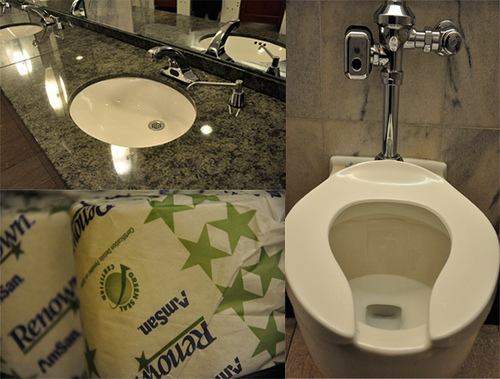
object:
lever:
[436, 20, 462, 60]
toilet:
[286, 1, 498, 377]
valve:
[333, 3, 466, 168]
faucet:
[143, 43, 200, 91]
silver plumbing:
[346, 0, 463, 162]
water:
[367, 300, 403, 330]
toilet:
[277, 131, 499, 376]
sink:
[1, 0, 58, 42]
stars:
[140, 187, 281, 358]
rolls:
[0, 195, 285, 372]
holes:
[243, 35, 278, 60]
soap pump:
[255, 40, 282, 78]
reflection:
[10, 16, 66, 81]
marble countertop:
[6, 19, 283, 187]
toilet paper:
[0, 179, 288, 379]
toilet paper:
[2, 193, 87, 376]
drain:
[144, 113, 165, 133]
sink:
[194, 22, 289, 82]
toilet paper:
[68, 199, 294, 351]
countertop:
[0, 2, 285, 189]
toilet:
[299, 77, 483, 376]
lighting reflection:
[3, 32, 217, 182]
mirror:
[0, 1, 285, 80]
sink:
[0, 1, 285, 189]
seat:
[308, 283, 339, 314]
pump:
[163, 67, 293, 159]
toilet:
[286, 151, 497, 376]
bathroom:
[290, 5, 498, 377]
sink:
[66, 70, 199, 150]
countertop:
[174, 82, 286, 155]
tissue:
[6, 190, 283, 377]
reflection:
[168, 110, 246, 181]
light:
[199, 122, 211, 132]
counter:
[1, 0, 283, 188]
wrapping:
[3, 190, 285, 370]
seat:
[281, 153, 500, 374]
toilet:
[278, 157, 500, 355]